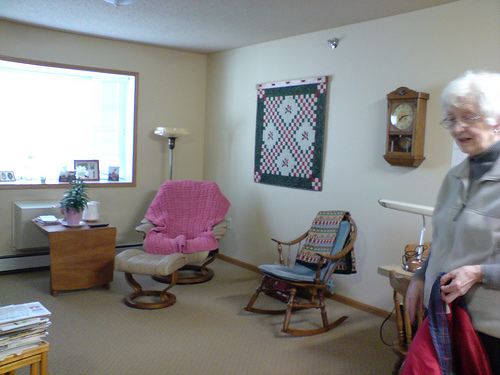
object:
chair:
[243, 208, 358, 337]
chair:
[115, 179, 231, 313]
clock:
[382, 85, 428, 169]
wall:
[0, 0, 499, 322]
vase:
[64, 205, 84, 225]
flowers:
[62, 165, 88, 199]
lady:
[403, 70, 499, 375]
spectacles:
[440, 113, 479, 129]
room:
[0, 0, 500, 375]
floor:
[0, 249, 424, 375]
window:
[1, 55, 138, 187]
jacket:
[393, 268, 493, 374]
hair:
[439, 72, 499, 121]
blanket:
[141, 181, 230, 255]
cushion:
[256, 261, 320, 281]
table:
[33, 216, 116, 295]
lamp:
[146, 118, 191, 180]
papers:
[0, 298, 54, 318]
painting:
[250, 75, 331, 190]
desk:
[378, 262, 412, 297]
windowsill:
[15, 177, 63, 185]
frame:
[133, 73, 137, 186]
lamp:
[375, 198, 439, 273]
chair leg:
[280, 288, 334, 337]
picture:
[71, 156, 103, 184]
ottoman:
[110, 249, 187, 311]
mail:
[36, 209, 63, 230]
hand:
[438, 266, 478, 304]